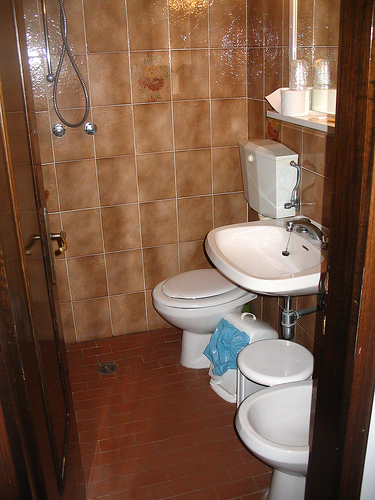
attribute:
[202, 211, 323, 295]
porcelain sink — small, white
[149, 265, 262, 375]
white toilet — closed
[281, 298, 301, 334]
pipes — silver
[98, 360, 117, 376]
plughole — drain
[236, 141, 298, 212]
tank — white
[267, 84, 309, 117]
roll — toilet paper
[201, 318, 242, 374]
bag container — white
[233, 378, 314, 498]
toilet — bathroom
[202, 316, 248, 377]
bag — blue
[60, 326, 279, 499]
floor — smooth, red, brick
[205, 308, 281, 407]
basket — small, plastic, white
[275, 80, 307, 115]
toilet paper — extra rolls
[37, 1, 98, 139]
shower faucet — silver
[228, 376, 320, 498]
bidet — white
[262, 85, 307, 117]
toilet paper — white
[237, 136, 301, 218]
cistern — rectangular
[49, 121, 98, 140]
knobs — round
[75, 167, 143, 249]
tiles — brown, square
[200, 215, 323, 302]
washbasin — white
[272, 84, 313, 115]
paper roll — white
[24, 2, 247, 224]
tiles — glossy, brown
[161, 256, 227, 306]
seat lid — toilet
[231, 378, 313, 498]
bidet — white, shiny, porcelain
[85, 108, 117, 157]
water knob — Cold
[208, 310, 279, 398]
garbage can — white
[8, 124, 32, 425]
door — wooden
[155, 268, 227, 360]
toilet — white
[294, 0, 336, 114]
mirror — clean, shiny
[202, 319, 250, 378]
plastic bag — green 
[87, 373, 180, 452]
tiles — reddish brown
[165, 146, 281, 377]
toilet — white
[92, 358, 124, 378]
drain — small, brass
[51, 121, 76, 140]
water — hot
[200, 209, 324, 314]
sink — square, white